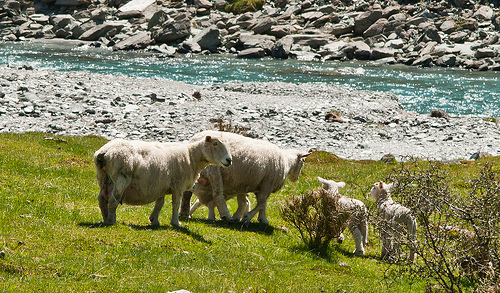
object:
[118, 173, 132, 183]
spots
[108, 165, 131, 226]
legs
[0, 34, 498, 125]
river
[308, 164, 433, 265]
calf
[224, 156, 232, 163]
nose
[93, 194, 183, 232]
feet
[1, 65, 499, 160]
river bed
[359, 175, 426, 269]
sheep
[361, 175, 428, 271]
baby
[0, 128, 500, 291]
grass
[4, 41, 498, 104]
water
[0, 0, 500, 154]
rocks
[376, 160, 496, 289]
trees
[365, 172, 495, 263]
bushes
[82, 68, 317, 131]
beach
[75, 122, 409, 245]
family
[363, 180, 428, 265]
lambs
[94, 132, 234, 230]
sheep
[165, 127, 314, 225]
sheep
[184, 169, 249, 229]
lambs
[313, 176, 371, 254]
lamb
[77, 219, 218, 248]
shadows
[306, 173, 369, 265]
sheep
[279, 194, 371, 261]
shrub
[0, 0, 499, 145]
bank